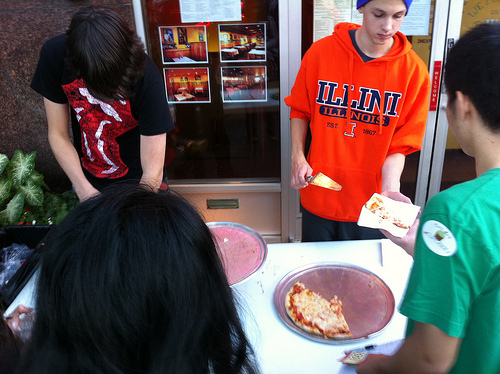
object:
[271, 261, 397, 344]
platter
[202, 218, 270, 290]
platter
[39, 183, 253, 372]
head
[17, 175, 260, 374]
woman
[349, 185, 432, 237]
piece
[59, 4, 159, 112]
hair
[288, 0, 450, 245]
door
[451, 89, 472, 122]
ear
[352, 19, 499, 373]
boy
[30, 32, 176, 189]
black shirt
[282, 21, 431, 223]
hoodie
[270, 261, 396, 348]
pot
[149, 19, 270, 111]
pictures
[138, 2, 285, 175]
window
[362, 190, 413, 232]
pizza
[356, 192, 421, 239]
napkin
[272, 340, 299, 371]
white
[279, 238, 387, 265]
table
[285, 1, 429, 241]
boy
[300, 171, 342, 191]
spatula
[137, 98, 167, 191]
arms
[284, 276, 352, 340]
sauce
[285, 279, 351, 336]
pizza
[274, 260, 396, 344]
pan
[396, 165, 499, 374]
green t-shirt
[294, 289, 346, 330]
yellow cheese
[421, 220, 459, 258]
sticker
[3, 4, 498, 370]
building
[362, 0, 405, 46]
head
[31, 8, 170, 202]
boy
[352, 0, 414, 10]
hat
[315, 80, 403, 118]
letters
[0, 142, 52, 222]
plant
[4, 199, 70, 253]
pot